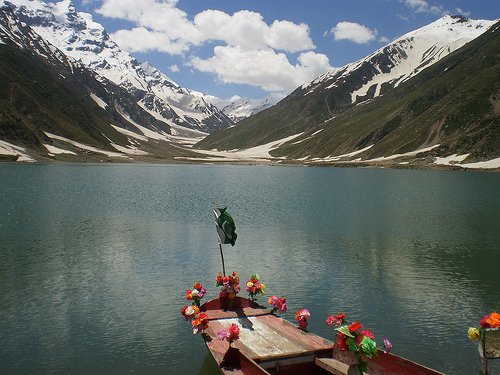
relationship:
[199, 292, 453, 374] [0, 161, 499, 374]
boat in water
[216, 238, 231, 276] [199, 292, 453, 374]
pole on boat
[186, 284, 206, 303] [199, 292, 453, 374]
bouquet on boat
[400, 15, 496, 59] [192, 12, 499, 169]
snow on mountain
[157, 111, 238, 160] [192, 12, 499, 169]
valley between mountain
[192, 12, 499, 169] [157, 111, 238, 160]
mountain with valley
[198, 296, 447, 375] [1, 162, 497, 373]
boat on lake